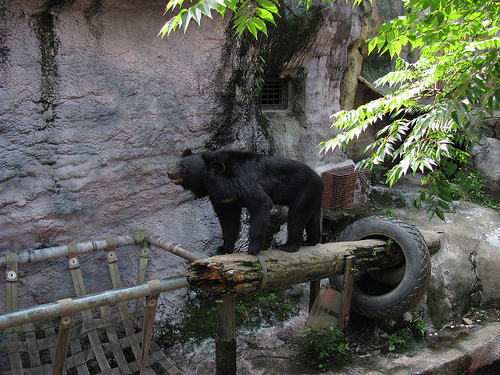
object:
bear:
[163, 145, 325, 255]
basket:
[316, 158, 359, 221]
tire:
[328, 215, 432, 325]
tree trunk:
[183, 227, 441, 305]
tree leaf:
[382, 145, 395, 158]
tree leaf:
[353, 125, 362, 139]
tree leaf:
[348, 128, 355, 142]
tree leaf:
[366, 100, 375, 115]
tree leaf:
[323, 140, 332, 153]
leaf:
[410, 158, 420, 178]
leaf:
[394, 128, 409, 138]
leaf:
[377, 111, 384, 121]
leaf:
[367, 116, 374, 126]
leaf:
[362, 143, 372, 153]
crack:
[465, 240, 485, 310]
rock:
[366, 185, 484, 341]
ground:
[1, 107, 483, 372]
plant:
[263, 290, 275, 308]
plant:
[236, 300, 249, 318]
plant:
[198, 302, 218, 321]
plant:
[243, 291, 259, 302]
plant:
[199, 320, 218, 335]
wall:
[1, 1, 441, 332]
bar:
[260, 96, 282, 100]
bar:
[258, 90, 280, 96]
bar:
[260, 84, 282, 90]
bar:
[263, 78, 269, 105]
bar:
[270, 75, 274, 102]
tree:
[153, 0, 500, 222]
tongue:
[167, 171, 181, 184]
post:
[212, 305, 243, 372]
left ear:
[176, 147, 192, 157]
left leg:
[209, 207, 241, 250]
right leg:
[242, 204, 274, 253]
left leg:
[309, 190, 331, 247]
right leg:
[287, 201, 306, 254]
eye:
[175, 160, 188, 171]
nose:
[165, 166, 180, 178]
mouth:
[170, 179, 180, 187]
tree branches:
[154, 0, 500, 223]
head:
[167, 146, 205, 200]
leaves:
[252, 253, 271, 280]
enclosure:
[4, 2, 498, 372]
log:
[193, 231, 389, 299]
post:
[337, 255, 354, 338]